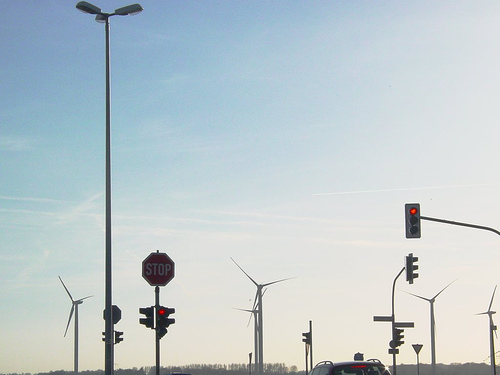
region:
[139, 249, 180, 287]
the stop sign is on a metal pole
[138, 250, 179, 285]
the sign is red and white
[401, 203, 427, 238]
the stop light is red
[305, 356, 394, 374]
a car is at the light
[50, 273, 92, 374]
the wind mills are white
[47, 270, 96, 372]
the produce electricity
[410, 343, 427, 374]
a yeild sign is in the distance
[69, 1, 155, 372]
Street light on the corner by the stop sign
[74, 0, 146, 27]
three lights are attached to the pole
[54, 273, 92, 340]
each wind mill has 3 propeller blades on it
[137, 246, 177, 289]
red and white stop sign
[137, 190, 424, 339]
two traffic lights showing red lights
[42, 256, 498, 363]
windmills in the background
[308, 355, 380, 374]
top of car driving down road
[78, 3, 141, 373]
street light next to stop sign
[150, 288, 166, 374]
pole stop sign is on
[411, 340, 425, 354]
triangle shaped traffic sign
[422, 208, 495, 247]
pole holding up traffic light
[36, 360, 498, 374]
tree line along horizon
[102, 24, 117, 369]
pole that street lights are on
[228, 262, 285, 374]
windmill structure standing up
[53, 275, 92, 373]
windmill structure standing up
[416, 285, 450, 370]
windmill structure standing up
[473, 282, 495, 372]
windmill structure standing up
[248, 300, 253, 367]
windmill structure standing up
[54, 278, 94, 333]
propellor on wind mill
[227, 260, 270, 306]
propellor on wind mill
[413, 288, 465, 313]
propellor on wind mill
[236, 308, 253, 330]
propellor on wind mill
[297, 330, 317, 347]
traffic light on pole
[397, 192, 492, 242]
a traffic light on edge of pole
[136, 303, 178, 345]
two traffic lights on a pole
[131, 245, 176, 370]
a STOP sign above a traffic light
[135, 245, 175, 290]
STOP sign with white letters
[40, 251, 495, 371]
windmills on side a road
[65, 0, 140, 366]
three lights on a pole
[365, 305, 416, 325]
two street signs on a traffic light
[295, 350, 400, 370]
the roof of a car is tan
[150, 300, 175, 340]
a traffic light in red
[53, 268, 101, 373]
a windmill has three propellers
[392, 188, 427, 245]
a red overhead stop light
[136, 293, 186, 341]
a red stop light on a pole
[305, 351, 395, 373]
the top of a car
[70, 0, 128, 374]
a tall street light pole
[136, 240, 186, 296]
a red stop sign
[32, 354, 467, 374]
a row of trees on the horizon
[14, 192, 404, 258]
condensation trails from a passing plane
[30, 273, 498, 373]
a row of wind mills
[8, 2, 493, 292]
a mostly clear blue sky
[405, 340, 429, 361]
a triangular traffic sign